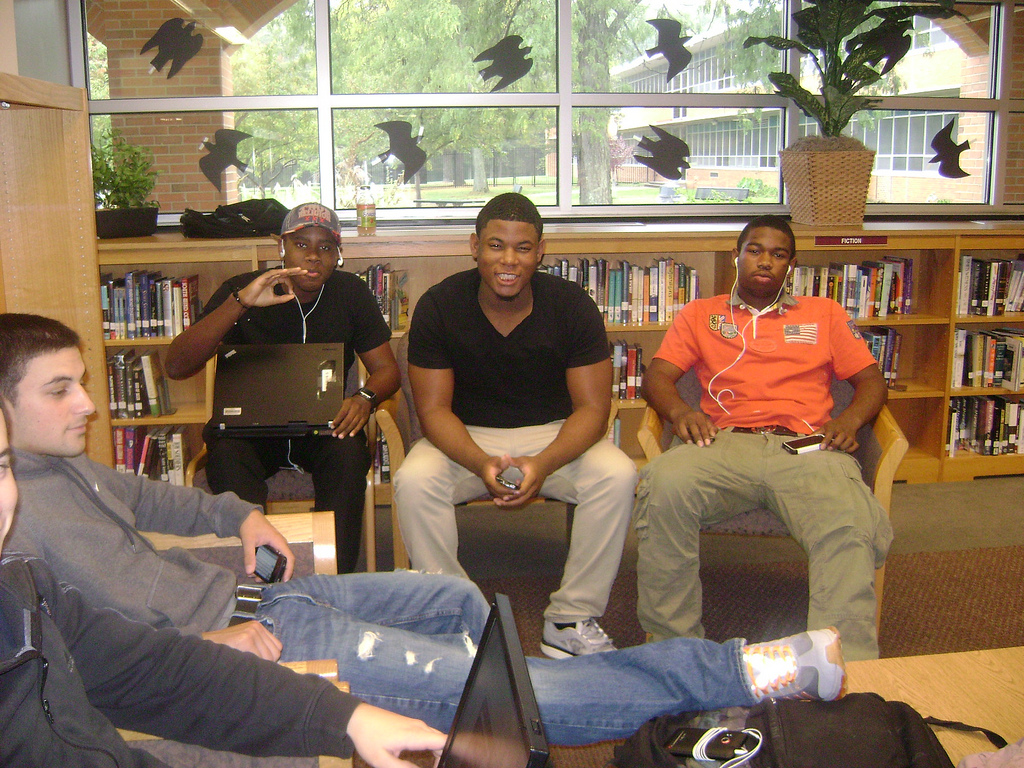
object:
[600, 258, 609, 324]
book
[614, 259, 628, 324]
book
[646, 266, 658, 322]
book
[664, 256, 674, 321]
book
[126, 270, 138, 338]
book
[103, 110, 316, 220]
window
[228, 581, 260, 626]
belt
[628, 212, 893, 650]
guy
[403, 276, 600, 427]
shirt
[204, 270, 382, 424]
shirt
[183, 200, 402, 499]
guy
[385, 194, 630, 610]
guy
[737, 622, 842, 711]
shoe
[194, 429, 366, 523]
lap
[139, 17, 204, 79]
bat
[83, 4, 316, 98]
window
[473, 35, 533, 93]
bat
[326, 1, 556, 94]
window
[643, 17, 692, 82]
bat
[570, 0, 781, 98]
window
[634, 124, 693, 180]
bat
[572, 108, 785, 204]
window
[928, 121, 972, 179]
bat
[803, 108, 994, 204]
window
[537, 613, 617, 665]
foot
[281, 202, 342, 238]
baseball cap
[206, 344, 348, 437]
laptop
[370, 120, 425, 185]
bird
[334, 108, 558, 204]
window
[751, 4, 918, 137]
plant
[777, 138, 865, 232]
wicker basket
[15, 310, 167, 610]
man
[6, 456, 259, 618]
jacket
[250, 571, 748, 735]
jeans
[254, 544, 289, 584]
cell phone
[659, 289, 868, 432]
shirt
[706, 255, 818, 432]
earphones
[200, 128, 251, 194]
birds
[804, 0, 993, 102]
windows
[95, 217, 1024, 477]
shelf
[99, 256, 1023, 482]
books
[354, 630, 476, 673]
marks